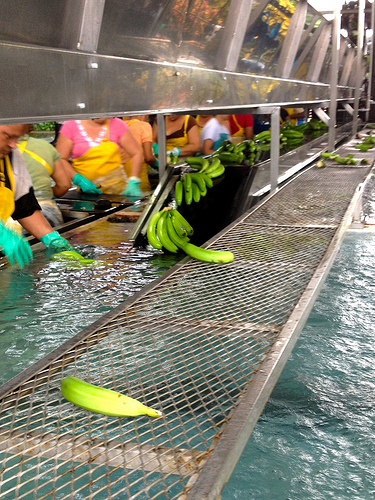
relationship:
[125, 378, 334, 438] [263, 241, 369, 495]
object in water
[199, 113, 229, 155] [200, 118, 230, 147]
woman in white shirt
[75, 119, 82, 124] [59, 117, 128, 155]
dot on shirt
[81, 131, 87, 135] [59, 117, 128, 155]
dot on shirt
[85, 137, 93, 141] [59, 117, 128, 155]
dot on shirt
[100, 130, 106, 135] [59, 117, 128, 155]
dot on shirt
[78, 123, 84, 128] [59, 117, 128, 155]
dot on shirt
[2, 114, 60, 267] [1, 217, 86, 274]
people wearing gloves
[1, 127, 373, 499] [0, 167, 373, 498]
shelf over water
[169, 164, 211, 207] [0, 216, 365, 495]
bananas on rack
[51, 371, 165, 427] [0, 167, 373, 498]
banana over water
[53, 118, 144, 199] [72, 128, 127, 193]
person wearing yellow apron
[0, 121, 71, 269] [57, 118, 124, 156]
woman wearing shirt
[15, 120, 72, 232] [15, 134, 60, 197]
woman wearing green shirt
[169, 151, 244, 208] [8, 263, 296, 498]
bananas on rack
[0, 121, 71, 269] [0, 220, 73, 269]
woman wearing gloves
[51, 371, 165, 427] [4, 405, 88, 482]
banana on rack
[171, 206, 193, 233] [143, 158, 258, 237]
banana in a bucket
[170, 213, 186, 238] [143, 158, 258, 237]
banana in a bucket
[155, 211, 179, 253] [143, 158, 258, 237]
banana in a bucket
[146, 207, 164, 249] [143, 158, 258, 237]
banana in a bucket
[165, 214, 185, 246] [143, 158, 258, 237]
banana in a bucket